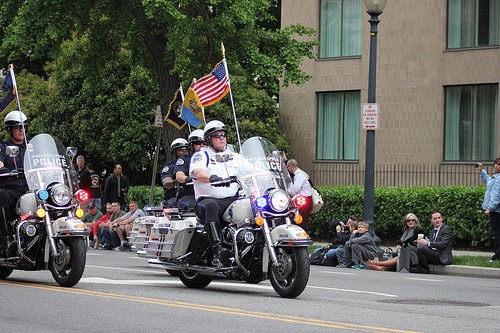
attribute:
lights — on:
[35, 188, 50, 200]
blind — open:
[437, 95, 493, 154]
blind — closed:
[321, 93, 363, 160]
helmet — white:
[206, 117, 225, 129]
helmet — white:
[187, 127, 202, 142]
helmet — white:
[170, 135, 187, 147]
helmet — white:
[2, 106, 29, 126]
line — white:
[348, 249, 462, 289]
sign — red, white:
[361, 103, 378, 130]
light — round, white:
[266, 184, 293, 213]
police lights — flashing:
[35, 188, 310, 228]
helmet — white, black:
[198, 119, 230, 136]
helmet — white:
[192, 115, 217, 134]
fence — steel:
[306, 160, 498, 191]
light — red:
[288, 189, 310, 209]